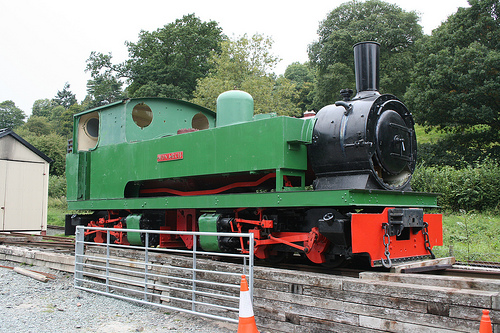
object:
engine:
[63, 40, 458, 274]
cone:
[234, 275, 259, 332]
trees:
[313, 0, 423, 103]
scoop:
[349, 207, 458, 275]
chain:
[365, 223, 402, 271]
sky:
[32, 12, 142, 71]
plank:
[1, 245, 499, 331]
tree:
[410, 0, 496, 131]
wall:
[329, 278, 402, 323]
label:
[157, 150, 184, 163]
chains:
[421, 221, 438, 261]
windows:
[131, 101, 154, 128]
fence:
[75, 223, 257, 323]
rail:
[74, 224, 256, 238]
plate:
[351, 214, 443, 268]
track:
[28, 237, 88, 249]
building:
[1, 126, 53, 236]